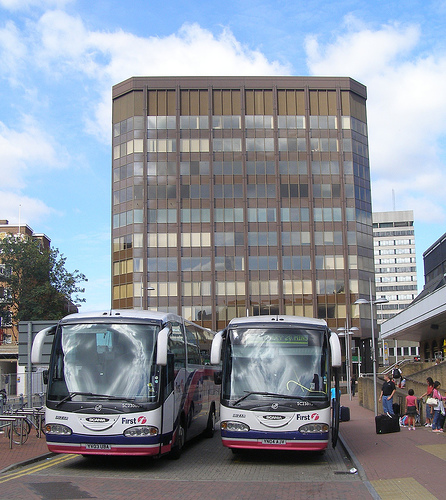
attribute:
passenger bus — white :
[219, 297, 326, 462]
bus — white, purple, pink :
[215, 315, 341, 451]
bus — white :
[40, 309, 221, 461]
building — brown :
[106, 72, 378, 347]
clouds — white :
[4, 9, 113, 213]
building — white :
[370, 205, 418, 319]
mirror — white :
[27, 326, 51, 362]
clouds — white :
[1, 0, 442, 78]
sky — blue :
[0, 1, 446, 311]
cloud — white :
[294, 17, 444, 171]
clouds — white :
[1, 0, 445, 315]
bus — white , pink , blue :
[208, 310, 346, 457]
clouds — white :
[320, 33, 394, 96]